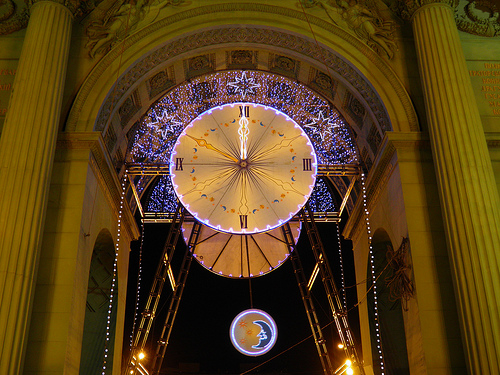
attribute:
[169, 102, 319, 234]
clock — suspended, golden, on time, tan, lit up, colorful, festive, ornate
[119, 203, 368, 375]
scaffolding — silver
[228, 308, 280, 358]
sun and moon — round, lit, festive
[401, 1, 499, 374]
pillar — large, stone, for support, tall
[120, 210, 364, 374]
sky — black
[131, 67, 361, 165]
display — white, blue, illuminated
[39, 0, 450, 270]
wall — stone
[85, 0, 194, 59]
statue — engraved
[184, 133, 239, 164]
hand — for minutes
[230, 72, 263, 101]
star — illuminated, light purple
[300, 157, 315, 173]
3 — roman numeral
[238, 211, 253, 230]
6 — roman numeral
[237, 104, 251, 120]
12 — roman numeral